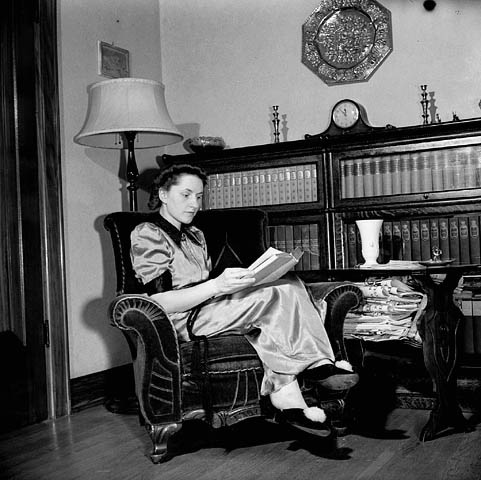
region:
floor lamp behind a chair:
[63, 51, 200, 203]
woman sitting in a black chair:
[160, 148, 355, 453]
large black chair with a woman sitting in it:
[126, 210, 348, 435]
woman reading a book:
[146, 162, 315, 429]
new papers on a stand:
[343, 280, 419, 354]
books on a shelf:
[348, 155, 477, 197]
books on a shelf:
[209, 166, 322, 201]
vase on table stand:
[353, 217, 390, 281]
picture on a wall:
[82, 26, 149, 78]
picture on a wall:
[294, 7, 468, 105]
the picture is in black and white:
[0, 0, 478, 471]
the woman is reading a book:
[128, 152, 352, 420]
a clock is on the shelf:
[306, 91, 369, 138]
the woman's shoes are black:
[247, 330, 365, 442]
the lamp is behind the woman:
[79, 60, 180, 198]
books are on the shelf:
[202, 142, 475, 241]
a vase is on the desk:
[336, 198, 402, 273]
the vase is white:
[334, 210, 396, 269]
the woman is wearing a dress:
[131, 208, 341, 365]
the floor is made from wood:
[0, 398, 472, 478]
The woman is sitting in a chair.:
[102, 161, 363, 464]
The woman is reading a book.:
[201, 238, 313, 294]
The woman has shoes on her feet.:
[248, 353, 352, 440]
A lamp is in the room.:
[59, 34, 211, 210]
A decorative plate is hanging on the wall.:
[280, 0, 413, 89]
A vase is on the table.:
[343, 202, 394, 269]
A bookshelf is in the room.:
[154, 137, 475, 363]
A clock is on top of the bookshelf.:
[277, 92, 417, 140]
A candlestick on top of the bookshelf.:
[249, 92, 293, 142]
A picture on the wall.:
[87, 12, 137, 79]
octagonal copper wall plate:
[295, 8, 400, 94]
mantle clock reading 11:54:
[300, 95, 393, 144]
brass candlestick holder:
[262, 100, 282, 144]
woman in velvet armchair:
[112, 151, 371, 464]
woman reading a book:
[120, 157, 328, 365]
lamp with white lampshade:
[68, 68, 188, 199]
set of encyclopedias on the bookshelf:
[341, 153, 479, 201]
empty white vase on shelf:
[352, 210, 386, 268]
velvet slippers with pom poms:
[261, 390, 337, 447]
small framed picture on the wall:
[93, 38, 141, 79]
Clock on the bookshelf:
[319, 95, 371, 130]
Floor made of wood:
[51, 434, 98, 470]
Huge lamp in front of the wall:
[76, 75, 173, 204]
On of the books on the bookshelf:
[378, 151, 393, 195]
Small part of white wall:
[188, 15, 244, 77]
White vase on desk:
[352, 210, 387, 269]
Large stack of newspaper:
[374, 283, 419, 337]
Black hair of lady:
[156, 165, 189, 175]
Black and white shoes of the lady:
[285, 408, 328, 440]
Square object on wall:
[94, 40, 132, 76]